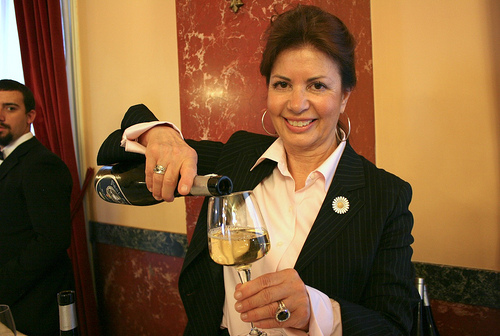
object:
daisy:
[332, 195, 351, 216]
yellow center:
[338, 201, 344, 209]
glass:
[205, 191, 271, 335]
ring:
[274, 301, 291, 322]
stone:
[281, 312, 288, 318]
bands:
[150, 165, 167, 175]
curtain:
[12, 1, 106, 334]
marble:
[174, 1, 261, 132]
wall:
[73, 0, 496, 273]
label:
[94, 175, 131, 205]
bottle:
[96, 163, 232, 206]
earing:
[262, 108, 277, 138]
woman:
[96, 7, 427, 335]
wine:
[210, 234, 269, 268]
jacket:
[100, 102, 425, 335]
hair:
[259, 5, 358, 88]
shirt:
[119, 118, 348, 334]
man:
[0, 78, 74, 333]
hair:
[1, 80, 37, 114]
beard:
[1, 132, 14, 150]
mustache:
[3, 121, 10, 129]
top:
[217, 175, 237, 197]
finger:
[239, 299, 304, 322]